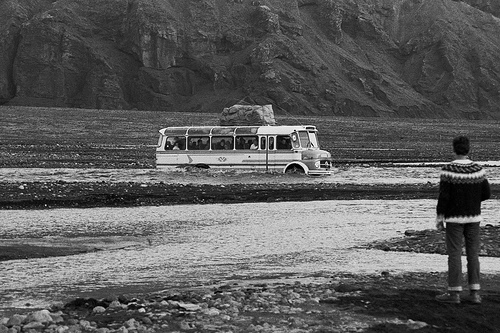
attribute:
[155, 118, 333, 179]
bus — old, white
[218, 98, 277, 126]
cargo — large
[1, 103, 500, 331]
ground — very rocky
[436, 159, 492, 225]
sweater — patterned, big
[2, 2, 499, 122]
hill — in the background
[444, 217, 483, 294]
pants — rolled up, dark, folded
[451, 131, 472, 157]
hair — short, dark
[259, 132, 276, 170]
door — closed